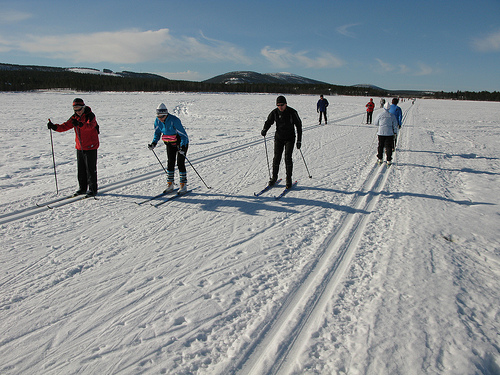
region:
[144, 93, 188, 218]
girl skiing in blue jacket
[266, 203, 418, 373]
trackings in the snow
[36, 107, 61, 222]
ski pole in right hand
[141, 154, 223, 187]
poles in each hand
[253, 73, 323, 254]
man in dark jacket on skis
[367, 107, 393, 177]
person going in opposite direction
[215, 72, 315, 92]
mountains in the distance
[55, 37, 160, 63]
clouds in the sky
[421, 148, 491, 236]
shadows on the snow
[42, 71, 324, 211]
group of people cross country sking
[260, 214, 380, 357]
track in snow from sking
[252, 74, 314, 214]
man in black ski suit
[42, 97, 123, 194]
person wearing red coat holding ski poles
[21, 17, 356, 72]
white wispy clouds in distance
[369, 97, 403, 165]
person in white coat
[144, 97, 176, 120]
white hat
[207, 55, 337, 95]
distant dark hills on horizon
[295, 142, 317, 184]
ski pole with pointed end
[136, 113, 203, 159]
blue ski jacket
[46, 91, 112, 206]
woman wearing red and black jacket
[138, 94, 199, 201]
woman wearing blue jacket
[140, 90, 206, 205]
woman wearing white beanie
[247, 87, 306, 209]
man riding skiis on the slope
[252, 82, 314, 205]
man wearing black jacket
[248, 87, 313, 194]
man wearing black pants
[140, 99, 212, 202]
woman wearing pink fannie pack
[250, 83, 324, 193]
man wearing dark sunglasses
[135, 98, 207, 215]
woman on skiis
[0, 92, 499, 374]
a large snowy field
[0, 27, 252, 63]
a large group of clouds in the sky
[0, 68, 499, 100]
a large wooded area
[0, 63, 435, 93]
a mountainous landscape in the background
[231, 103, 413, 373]
ski tracks in the snow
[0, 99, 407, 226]
ski tracks in the snow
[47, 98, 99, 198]
a person cross-country skiing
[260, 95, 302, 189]
a person cross-country skiing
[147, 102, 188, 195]
a person cross-country skiing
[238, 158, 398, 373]
ski tracks in the snow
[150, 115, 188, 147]
blue snow jacket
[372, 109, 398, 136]
white snow jacket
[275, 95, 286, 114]
man has sunglasses and a beanie on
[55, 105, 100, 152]
red and black jacket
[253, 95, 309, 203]
a man is skiing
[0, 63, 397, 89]
mountains and trees in the distance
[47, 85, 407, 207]
a group of skiers on the snow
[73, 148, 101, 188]
pants are black in color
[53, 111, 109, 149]
the coat is red in color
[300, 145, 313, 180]
a black ski pole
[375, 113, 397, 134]
the jacket is white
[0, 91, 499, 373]
the snow is white and covers the ground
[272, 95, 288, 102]
the hat is black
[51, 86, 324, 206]
a group of people skiing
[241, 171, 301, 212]
skis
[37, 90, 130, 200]
the person wearing a red jacket in the front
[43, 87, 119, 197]
A person wearing a red jacket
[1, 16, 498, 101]
The cloudy sky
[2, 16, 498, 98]
A cloudy sky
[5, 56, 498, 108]
the mountain range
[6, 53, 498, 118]
A mountain range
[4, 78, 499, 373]
The snow on the ground